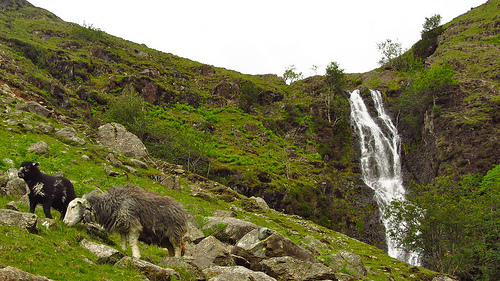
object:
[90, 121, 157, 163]
boulder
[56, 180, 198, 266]
sheep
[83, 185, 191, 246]
coat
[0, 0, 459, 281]
mountainside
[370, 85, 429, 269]
streams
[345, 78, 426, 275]
waterfall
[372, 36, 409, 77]
bush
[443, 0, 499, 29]
hilltop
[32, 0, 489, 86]
sky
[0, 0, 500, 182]
hill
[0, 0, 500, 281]
grass